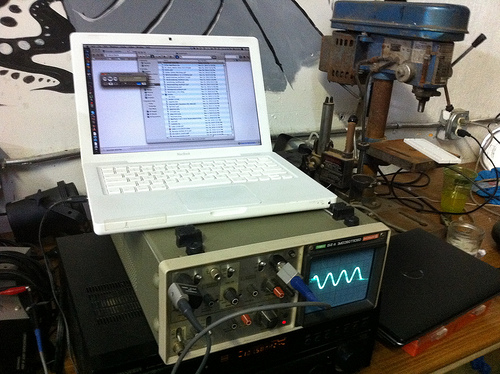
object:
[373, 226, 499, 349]
laptop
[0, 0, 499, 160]
wall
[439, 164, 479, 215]
glass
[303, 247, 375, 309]
screen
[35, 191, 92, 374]
cord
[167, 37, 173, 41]
webcam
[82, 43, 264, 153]
computer screen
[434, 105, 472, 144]
outlet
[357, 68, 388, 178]
drill press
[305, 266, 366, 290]
lines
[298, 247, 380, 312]
oscilloscope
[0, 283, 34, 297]
clip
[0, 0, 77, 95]
designs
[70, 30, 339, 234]
laptop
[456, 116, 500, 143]
cords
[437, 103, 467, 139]
box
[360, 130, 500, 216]
wires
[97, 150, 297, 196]
keyboard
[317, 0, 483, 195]
machine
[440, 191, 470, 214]
water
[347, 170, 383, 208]
plugs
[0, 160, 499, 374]
table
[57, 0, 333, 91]
painting